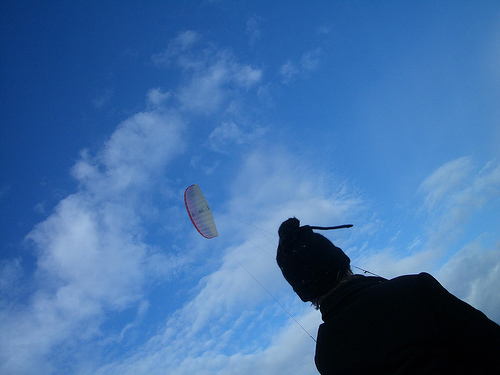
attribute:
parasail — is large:
[181, 182, 221, 241]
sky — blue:
[6, 8, 163, 211]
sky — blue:
[74, 88, 314, 165]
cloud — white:
[175, 42, 238, 88]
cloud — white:
[110, 127, 161, 194]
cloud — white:
[59, 185, 119, 238]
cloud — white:
[416, 164, 451, 235]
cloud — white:
[141, 301, 216, 347]